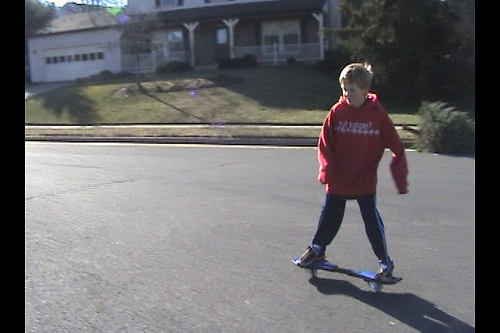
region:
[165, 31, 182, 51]
Large window on a house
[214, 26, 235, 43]
Large window on a house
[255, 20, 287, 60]
Large window on a house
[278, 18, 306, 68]
Large window on a house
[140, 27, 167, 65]
Large window on a house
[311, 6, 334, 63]
Large white post on porch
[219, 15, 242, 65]
Large white post on porch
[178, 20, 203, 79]
Large white post on porch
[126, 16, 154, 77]
Large white post on porch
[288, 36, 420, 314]
Small child on skateboard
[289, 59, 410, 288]
young boy on skateboard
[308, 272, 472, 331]
shadow cast by skater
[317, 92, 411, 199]
red hooded sweat shirt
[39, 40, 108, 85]
white garage door with windows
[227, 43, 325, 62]
white railing on front porch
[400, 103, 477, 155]
pine tree out for garbage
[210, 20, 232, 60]
brown front door of house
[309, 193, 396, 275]
blue sweatpants with white stripe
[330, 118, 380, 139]
white writing on sweat shirt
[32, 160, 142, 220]
crack in street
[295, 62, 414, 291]
a kid is on a skateboard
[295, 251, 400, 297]
a ripstick on concrete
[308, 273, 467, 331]
shadow of a boy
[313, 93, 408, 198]
a boy's red jacket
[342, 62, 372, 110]
head of a boy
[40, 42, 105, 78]
a white garage door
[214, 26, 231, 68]
front door on a home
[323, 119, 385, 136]
white pattern on a red shirt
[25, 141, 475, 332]
a stretch of asphalt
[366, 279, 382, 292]
wheel on a ripstick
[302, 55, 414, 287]
this is a person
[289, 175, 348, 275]
this is a person's leg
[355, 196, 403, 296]
this is a person's leg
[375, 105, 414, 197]
this is a person's hand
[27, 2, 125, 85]
this is a building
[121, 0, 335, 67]
this is a building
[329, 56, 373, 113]
this is a person's head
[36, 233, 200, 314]
this is the road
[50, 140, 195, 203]
this is the road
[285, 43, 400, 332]
Small child on a skatebpard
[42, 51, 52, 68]
Small window on a garage door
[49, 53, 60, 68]
Small window on a garage door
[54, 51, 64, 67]
Small window on a garage door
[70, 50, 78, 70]
Small window on a garage door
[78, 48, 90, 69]
Small window on a garage door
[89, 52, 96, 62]
Small window on a garage door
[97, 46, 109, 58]
Small window on a garage door